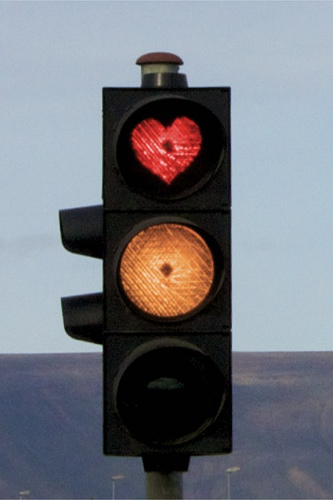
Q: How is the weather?
A: It is clear.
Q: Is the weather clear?
A: Yes, it is clear.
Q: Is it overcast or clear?
A: It is clear.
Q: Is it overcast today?
A: No, it is clear.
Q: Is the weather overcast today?
A: No, it is clear.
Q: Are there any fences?
A: No, there are no fences.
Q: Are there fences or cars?
A: No, there are no fences or cars.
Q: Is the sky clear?
A: Yes, the sky is clear.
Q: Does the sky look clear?
A: Yes, the sky is clear.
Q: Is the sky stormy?
A: No, the sky is clear.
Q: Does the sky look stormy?
A: No, the sky is clear.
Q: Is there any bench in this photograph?
A: No, there are no benches.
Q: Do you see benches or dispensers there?
A: No, there are no benches or dispensers.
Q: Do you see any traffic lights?
A: Yes, there is a traffic light.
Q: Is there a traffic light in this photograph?
A: Yes, there is a traffic light.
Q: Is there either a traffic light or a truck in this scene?
A: Yes, there is a traffic light.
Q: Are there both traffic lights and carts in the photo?
A: No, there is a traffic light but no carts.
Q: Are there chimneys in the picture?
A: No, there are no chimneys.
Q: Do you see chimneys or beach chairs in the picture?
A: No, there are no chimneys or beach chairs.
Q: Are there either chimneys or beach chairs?
A: No, there are no chimneys or beach chairs.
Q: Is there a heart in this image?
A: Yes, there is a heart.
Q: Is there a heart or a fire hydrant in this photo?
A: Yes, there is a heart.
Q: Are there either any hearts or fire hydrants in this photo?
A: Yes, there is a heart.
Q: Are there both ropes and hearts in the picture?
A: No, there is a heart but no ropes.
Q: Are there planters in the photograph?
A: No, there are no planters.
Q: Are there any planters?
A: No, there are no planters.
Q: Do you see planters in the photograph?
A: No, there are no planters.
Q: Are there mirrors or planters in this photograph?
A: No, there are no planters or mirrors.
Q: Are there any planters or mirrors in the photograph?
A: No, there are no planters or mirrors.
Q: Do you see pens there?
A: No, there are no pens.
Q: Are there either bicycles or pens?
A: No, there are no pens or bicycles.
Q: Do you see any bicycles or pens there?
A: No, there are no pens or bicycles.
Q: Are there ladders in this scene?
A: No, there are no ladders.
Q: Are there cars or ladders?
A: No, there are no ladders or cars.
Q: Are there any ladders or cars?
A: No, there are no ladders or cars.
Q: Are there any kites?
A: No, there are no kites.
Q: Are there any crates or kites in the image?
A: No, there are no kites or crates.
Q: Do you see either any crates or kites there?
A: No, there are no kites or crates.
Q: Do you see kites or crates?
A: No, there are no kites or crates.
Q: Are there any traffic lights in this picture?
A: Yes, there is a traffic light.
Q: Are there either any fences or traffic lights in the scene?
A: Yes, there is a traffic light.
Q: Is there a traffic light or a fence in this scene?
A: Yes, there is a traffic light.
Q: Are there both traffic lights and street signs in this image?
A: No, there is a traffic light but no street signs.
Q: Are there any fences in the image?
A: No, there are no fences.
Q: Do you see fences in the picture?
A: No, there are no fences.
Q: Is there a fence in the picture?
A: No, there are no fences.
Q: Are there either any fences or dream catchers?
A: No, there are no fences or dream catchers.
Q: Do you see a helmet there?
A: No, there are no helmets.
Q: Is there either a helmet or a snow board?
A: No, there are no helmets or snowboards.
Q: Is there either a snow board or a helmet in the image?
A: No, there are no helmets or snowboards.